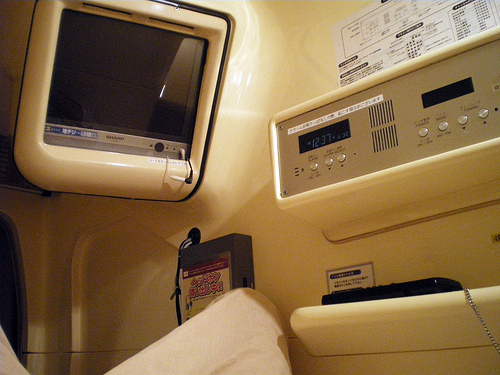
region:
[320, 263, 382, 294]
White and blue sign on the wall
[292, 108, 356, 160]
Black screen with blue display lights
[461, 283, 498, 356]
Gray curly cord connecting the technology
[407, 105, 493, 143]
Four round silver buttons on the machine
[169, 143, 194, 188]
Short white and black cords hanging down from the screen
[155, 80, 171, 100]
White light reflection on the black screen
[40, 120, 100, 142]
Blue and white label below the screen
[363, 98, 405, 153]
Two black vents on the wall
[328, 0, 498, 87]
Black and white sign above the machine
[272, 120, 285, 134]
Metal screw in the wall box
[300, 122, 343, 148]
time on the clock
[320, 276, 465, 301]
black remote on counter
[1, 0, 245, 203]
white monitor in room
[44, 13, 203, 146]
black screen on monitor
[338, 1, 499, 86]
white and black sign on wall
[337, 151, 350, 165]
silver button on radio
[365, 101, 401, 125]
speaker on the radio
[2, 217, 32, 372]
window in the room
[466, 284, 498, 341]
cord attached to remote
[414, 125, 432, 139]
silver button on the radio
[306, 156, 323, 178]
button on a machine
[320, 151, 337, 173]
button on a machine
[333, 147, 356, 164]
button on a machine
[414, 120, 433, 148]
button on a machine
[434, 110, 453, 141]
button on a machine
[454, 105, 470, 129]
button on a machine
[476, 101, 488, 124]
button on a machine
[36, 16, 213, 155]
screen of a machine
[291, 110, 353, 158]
screen of a machine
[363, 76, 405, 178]
speaker grill of a machine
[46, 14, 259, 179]
a display on the screen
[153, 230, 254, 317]
a box in the wall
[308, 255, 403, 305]
a part of paper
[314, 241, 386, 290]
a part of cover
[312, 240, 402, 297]
a cover to wall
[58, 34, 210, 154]
a dispaly in power off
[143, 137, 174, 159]
a black sensor in display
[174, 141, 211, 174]
a button to adjust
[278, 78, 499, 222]
a view of controls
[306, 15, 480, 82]
usage chart attached to wall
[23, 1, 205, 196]
TV MONITOR OVER BED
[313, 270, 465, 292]
BLACK REMOTE NEAR BED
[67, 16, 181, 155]
BLACK SCREEN OF MONITOR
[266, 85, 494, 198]
ELECTRONIC DEVICE OVER BED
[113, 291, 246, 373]
WHITE PILLOW OF BED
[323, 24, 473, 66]
WHITE DIAGRAM ON WALL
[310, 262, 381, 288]
SMALL STICKER BY REMOTE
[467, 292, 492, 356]
CORD ATTACHED TO REMOTE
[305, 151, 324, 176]
SILVER BUTTON ON DEVICE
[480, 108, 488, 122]
SILVER BUTTON ON DEVICE